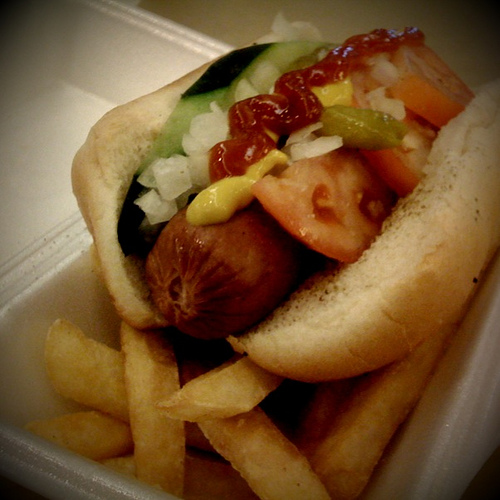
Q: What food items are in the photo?
A: A hot dog and french fries.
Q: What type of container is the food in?
A: Styrofoam.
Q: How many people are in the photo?
A: None.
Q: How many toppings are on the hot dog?
A: Six.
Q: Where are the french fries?
A: Under the hot dog.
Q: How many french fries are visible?
A: Eight.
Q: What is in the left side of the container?
A: Nothing.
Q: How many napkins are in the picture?
A: None.